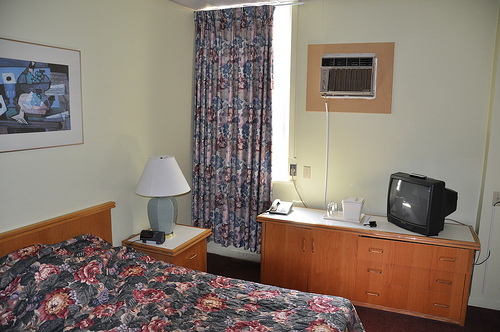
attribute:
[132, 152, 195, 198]
lamp shade — white lamp 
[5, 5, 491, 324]
room — hotel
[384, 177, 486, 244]
tv — black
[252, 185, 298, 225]
phone — white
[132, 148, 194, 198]
shade — white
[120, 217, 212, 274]
table — side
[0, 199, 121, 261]
cot — brown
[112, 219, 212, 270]
stand — brown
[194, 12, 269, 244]
drapes — floral pattern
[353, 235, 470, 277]
drawer — brown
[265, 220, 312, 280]
cabinet — wooden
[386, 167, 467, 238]
tv — small black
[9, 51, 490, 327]
room — hotel